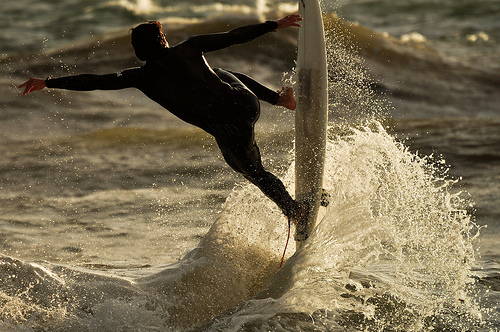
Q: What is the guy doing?
A: Surfing.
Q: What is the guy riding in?
A: The water.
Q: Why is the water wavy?
A: It is the ocean.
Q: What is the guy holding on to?
A: A surfboard.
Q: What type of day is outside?
A: Sunny.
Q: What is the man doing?
A: Surfing.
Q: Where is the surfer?
A: In the water.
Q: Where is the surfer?
A: Water.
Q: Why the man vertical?
A: Trying to balance.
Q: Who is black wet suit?
A: Surfer.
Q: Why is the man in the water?
A: To surf.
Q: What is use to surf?
A: Surfboard.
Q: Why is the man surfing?
A: Fun.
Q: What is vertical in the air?
A: The surfboard.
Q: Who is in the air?
A: The man.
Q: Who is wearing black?
A: The surfer.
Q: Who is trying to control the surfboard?
A: The surfer.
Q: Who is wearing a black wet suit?
A: The man.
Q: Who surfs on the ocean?
A: The man.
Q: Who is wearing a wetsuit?
A: A man.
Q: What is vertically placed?
A: A surfboard.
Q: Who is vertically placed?
A: A man.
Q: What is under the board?
A: Water.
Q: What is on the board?
A: Feet.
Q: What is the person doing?
A: Surfing.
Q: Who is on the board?
A: Man in wetsuit.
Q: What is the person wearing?
A: Wetsuit.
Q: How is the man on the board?
A: Balance.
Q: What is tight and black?
A: Wetsuit.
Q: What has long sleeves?
A: Wetsuit.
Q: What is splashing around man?
A: Water.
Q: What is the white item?
A: Surfboard.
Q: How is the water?
A: Rough.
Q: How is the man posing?
A: Arms out.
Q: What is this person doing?
A: Surfing.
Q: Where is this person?
A: The ocean.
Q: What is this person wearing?
A: Wetsuit.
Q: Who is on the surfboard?
A: Man.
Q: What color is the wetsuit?
A: Black.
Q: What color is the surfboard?
A: White.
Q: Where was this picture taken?
A: Ocean.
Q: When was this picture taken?
A: Daytime.